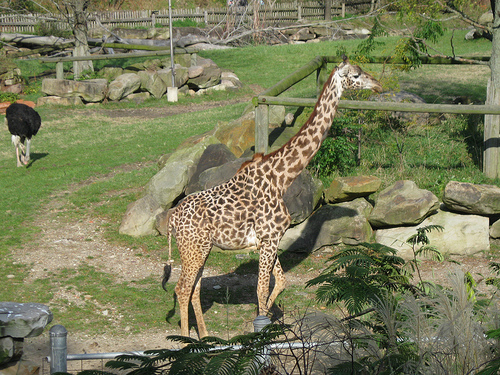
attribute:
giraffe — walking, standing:
[162, 54, 390, 348]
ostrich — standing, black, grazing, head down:
[5, 104, 41, 168]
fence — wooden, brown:
[1, 1, 373, 31]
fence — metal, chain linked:
[42, 315, 487, 375]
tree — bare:
[0, 1, 132, 81]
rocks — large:
[0, 20, 499, 367]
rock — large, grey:
[277, 196, 376, 255]